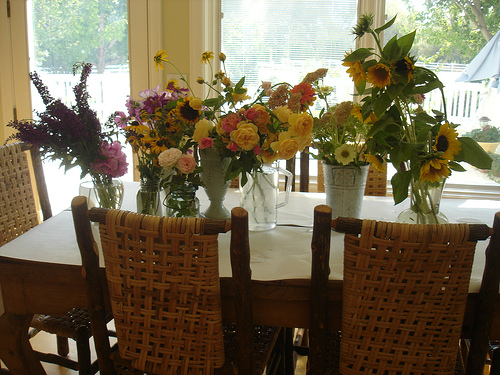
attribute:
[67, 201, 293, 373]
chair — wooden, woven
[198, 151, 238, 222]
vase — green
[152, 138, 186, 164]
flower — white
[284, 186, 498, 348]
chair — wooden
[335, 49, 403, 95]
flower — orange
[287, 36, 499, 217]
flower — yellow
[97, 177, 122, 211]
stems — green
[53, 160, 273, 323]
chair — wicker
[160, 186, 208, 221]
vase — clear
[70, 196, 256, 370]
chair — wooden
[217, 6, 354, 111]
blind — open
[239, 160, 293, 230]
vase — clear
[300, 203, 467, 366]
chair — wicker